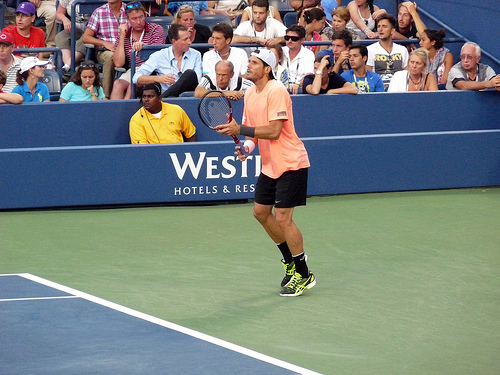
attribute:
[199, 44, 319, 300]
player — playing, male, standing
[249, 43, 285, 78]
cap — white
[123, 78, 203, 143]
man — black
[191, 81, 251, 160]
racket — red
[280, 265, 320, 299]
shoes — gray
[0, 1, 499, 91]
group — watching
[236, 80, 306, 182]
shirt — orange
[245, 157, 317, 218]
black shorts — here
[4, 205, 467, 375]
court — blue, white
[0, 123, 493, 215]
wall — blue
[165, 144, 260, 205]
writing — advertisement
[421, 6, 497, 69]
railing — mwtal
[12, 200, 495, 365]
floor — green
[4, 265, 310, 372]
lines — white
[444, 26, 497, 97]
man — bored